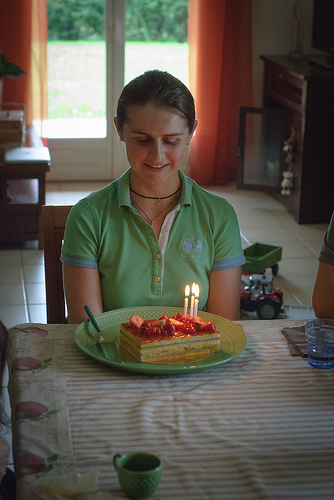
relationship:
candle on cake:
[178, 282, 193, 320] [115, 309, 226, 361]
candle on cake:
[194, 295, 202, 316] [115, 309, 226, 361]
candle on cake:
[191, 285, 198, 320] [115, 309, 226, 361]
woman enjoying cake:
[57, 66, 274, 322] [115, 309, 226, 361]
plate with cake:
[72, 297, 250, 373] [115, 309, 226, 361]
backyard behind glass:
[44, 0, 190, 136] [48, 0, 187, 131]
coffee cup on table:
[111, 447, 171, 496] [10, 314, 327, 497]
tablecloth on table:
[4, 316, 333, 487] [10, 314, 327, 497]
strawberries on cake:
[133, 312, 212, 335] [115, 309, 226, 361]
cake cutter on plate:
[80, 297, 121, 363] [72, 297, 250, 373]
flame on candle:
[183, 284, 188, 296] [184, 298, 189, 320]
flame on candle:
[193, 286, 198, 296] [191, 285, 198, 320]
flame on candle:
[193, 286, 200, 298] [194, 295, 202, 316]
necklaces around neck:
[127, 178, 182, 225] [133, 173, 185, 213]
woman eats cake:
[57, 66, 274, 322] [115, 309, 226, 361]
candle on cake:
[184, 298, 189, 320] [115, 309, 226, 361]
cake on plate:
[115, 309, 226, 361] [72, 297, 250, 373]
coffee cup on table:
[112, 451, 163, 500] [10, 314, 327, 497]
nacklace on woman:
[126, 183, 186, 198] [57, 66, 274, 322]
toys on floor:
[242, 238, 289, 319] [4, 177, 333, 317]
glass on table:
[304, 317, 333, 372] [10, 314, 327, 497]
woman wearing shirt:
[57, 66, 274, 322] [56, 175, 253, 316]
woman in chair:
[57, 66, 274, 322] [38, 191, 226, 317]